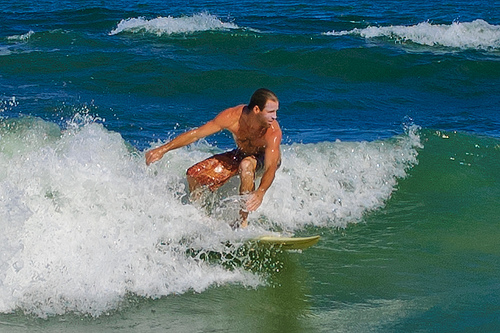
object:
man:
[146, 89, 282, 225]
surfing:
[146, 88, 320, 249]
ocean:
[0, 0, 494, 325]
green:
[381, 214, 489, 320]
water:
[425, 137, 499, 333]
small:
[109, 12, 237, 37]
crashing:
[108, 12, 237, 36]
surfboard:
[242, 236, 319, 250]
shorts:
[186, 148, 281, 191]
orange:
[199, 163, 228, 175]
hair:
[249, 88, 280, 111]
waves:
[0, 117, 126, 312]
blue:
[288, 50, 469, 96]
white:
[55, 151, 121, 219]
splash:
[64, 124, 124, 206]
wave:
[358, 20, 492, 49]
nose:
[290, 235, 320, 249]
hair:
[241, 138, 252, 146]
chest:
[238, 122, 263, 150]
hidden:
[215, 231, 262, 247]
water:
[121, 112, 207, 125]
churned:
[283, 135, 418, 226]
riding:
[0, 126, 422, 318]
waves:
[269, 141, 419, 227]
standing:
[146, 88, 319, 250]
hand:
[146, 148, 163, 165]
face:
[262, 101, 278, 127]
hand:
[247, 190, 262, 211]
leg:
[239, 160, 255, 217]